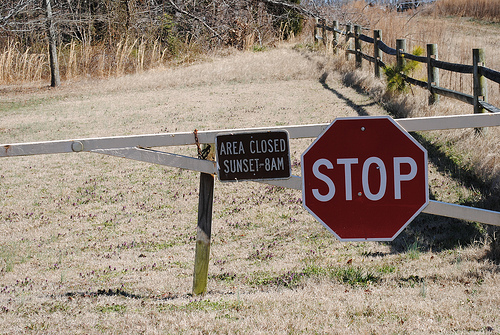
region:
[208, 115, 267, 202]
Black sign on railing.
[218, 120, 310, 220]
White writing on black sign.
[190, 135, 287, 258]
Sign says area closed sunset-8am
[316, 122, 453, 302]
Stop sign next to black sign.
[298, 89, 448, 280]
Stop sign is red.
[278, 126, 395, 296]
Sign says STOP in white writing.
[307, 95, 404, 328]
Sign has 8 sides.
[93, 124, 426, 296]
Chain around white railing.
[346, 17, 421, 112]
Wood fence on the right side.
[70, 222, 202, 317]
Grass is mostly dry and tan.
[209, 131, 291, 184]
AREA CLOSED SIGN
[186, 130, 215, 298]
POST ATTACHED TO GATE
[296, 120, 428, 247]
MOUNTED STOP SIGN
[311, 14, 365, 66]
GREY WOODEN FENCE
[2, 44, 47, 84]
TALL DRY TAN GRASS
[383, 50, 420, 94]
YOUNG PINE TREE NEAR FENCE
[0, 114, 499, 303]
GATE FOR PASTURE AREA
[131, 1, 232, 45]
DRY FALLEN TREES AND BRANCHES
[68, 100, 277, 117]
TAN DRIED GRASS IN AREA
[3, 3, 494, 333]
CLOSED PARK RECREATION AREA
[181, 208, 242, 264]
white paint on post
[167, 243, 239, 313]
yellow part on the post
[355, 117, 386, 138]
small screw in the sign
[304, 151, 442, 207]
white words on the sign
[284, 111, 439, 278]
red sign on the post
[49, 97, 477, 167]
long white post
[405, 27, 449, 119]
brown wooden post in the field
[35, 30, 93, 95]
tall gray tree trunk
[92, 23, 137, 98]
tall brown bushes in the field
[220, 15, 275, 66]
large brown stump in the ground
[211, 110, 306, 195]
A closed road sign.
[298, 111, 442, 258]
A red stop sign on a fence.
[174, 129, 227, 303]
A pole holding up a sign.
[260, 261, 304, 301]
A patch of dry grass.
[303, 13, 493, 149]
A long wooden fence.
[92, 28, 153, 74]
Wild brush growing on the side of a road.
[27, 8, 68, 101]
A long tree trunk.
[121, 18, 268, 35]
Lots of wild trees and plants.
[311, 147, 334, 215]
A large s on a stop sign.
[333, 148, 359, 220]
A large t on a stop sign.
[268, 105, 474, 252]
A red and white stop sign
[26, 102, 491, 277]
The fence is white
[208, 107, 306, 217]
The sign is black and white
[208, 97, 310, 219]
The sign reads Area Closed Sunset- 8AM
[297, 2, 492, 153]
A brown wooden fence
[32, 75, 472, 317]
Brown, dead grass in the enclosed area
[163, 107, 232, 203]
A chain connects the fence and a wooden post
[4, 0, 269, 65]
Trees and dry brush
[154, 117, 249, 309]
The bottom of the post is yellow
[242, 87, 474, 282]
The stop sign is bolted to the fence